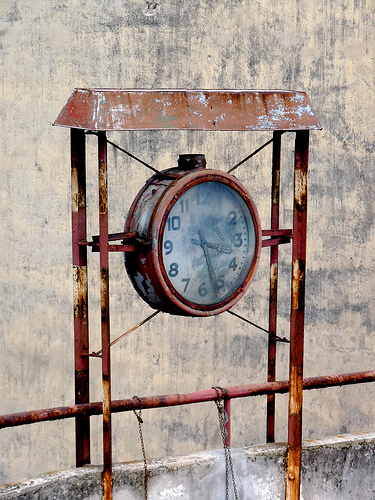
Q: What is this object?
A: Clock.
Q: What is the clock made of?
A: Metal.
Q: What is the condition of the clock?
A: Dirty.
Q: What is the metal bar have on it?
A: A chain.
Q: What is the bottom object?
A: Stone curb.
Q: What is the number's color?
A: Black.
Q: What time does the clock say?
A: 3:27.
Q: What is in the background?
A: Concrete wall.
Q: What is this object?
A: Clock.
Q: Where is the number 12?
A: On the clock.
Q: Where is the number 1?
A: On the clock.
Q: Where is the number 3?
A: On the clock.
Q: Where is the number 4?
A: On the clock.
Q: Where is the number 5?
A: On the clock.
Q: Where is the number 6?
A: On the clock.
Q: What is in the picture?
A: A clock.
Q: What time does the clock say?
A: 3:27.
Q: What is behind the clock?
A: A wall.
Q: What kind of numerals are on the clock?
A: Arabic,.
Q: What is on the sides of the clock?
A: Metal rods.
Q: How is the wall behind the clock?
A: Dirty.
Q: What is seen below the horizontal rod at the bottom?
A: Small chains.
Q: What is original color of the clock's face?
A: White.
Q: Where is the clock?
A: On posts.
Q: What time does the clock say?
A: 3:29.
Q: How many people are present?
A: 0.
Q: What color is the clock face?
A: White.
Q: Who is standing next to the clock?
A: Nobody.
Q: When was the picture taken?
A: Afternoon.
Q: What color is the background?
A: Gray.